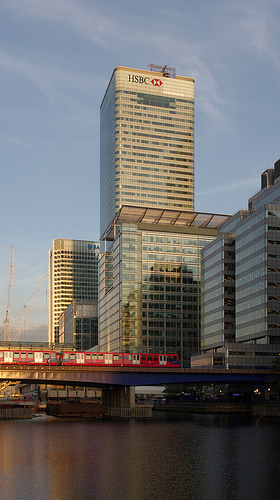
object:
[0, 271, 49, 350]
crane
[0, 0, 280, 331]
blue sky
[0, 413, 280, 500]
water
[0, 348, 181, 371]
train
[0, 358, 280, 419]
bridge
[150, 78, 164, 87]
sign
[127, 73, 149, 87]
writting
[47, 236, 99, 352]
building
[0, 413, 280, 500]
reflection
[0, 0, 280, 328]
cloud